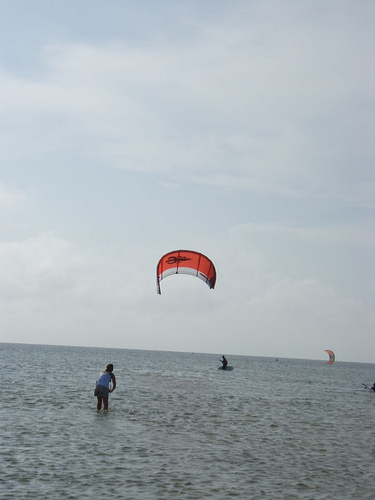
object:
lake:
[0, 337, 372, 499]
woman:
[94, 362, 118, 415]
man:
[219, 349, 226, 372]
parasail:
[154, 249, 218, 295]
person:
[266, 355, 297, 371]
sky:
[1, 0, 374, 364]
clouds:
[111, 73, 276, 178]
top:
[98, 372, 112, 388]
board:
[218, 364, 237, 374]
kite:
[156, 248, 215, 293]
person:
[220, 353, 228, 371]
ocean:
[0, 347, 374, 496]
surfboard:
[215, 365, 235, 370]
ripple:
[0, 340, 374, 498]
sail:
[326, 349, 333, 359]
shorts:
[96, 387, 109, 400]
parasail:
[321, 345, 337, 368]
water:
[0, 346, 374, 496]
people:
[95, 353, 228, 410]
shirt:
[94, 371, 112, 393]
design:
[168, 253, 200, 272]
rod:
[173, 246, 186, 275]